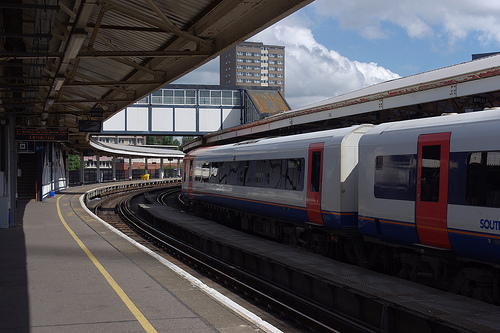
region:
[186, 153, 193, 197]
the door on a passenger train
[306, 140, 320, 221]
the door on a passenger train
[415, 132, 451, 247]
the door on a passenger train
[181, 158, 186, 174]
a window on a passenger train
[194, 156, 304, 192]
windows on a passenger train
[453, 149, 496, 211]
a window on a passenger train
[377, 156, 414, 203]
a window on a passenger train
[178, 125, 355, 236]
a car on a passenger train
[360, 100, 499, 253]
a car on a passenger train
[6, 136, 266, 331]
the loading ramp of a train station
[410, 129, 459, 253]
A red door on a metro train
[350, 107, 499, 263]
A blue, red and gray train car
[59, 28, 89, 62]
A ceiling light fixture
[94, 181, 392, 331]
Solid steel railroad tracks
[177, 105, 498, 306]
Two full train cars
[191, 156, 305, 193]
A set of windows on train car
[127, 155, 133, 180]
A gray support pole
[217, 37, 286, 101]
A tall brown residential building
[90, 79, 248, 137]
A white and gray walkway over the tracks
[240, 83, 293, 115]
A rusted angled roof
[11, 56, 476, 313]
a train in a train station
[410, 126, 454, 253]
door of train is red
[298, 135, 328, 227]
door of train is red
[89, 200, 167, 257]
edge of platform is white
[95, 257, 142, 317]
a white line on the platform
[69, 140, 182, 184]
columns supporting the roof of train station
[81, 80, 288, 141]
a bridge over the railroad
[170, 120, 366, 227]
car of train is white and blue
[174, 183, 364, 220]
side of train has a red stripe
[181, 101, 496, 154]
roof of train is white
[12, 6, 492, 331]
Photo taken during the day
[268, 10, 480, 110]
The sky is clear with clouds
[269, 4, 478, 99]
The clouds are fluffy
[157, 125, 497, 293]
Train on the track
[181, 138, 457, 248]
Red doors on the train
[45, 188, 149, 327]
Yellow lines on the platform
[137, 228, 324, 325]
Train tracks made of metal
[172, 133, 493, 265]
White and blue train with red doors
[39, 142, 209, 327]
Nobody on the platform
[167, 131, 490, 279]
The train is a passenger train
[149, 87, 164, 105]
window is next to window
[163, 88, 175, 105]
window is next to window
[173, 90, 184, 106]
window is next to window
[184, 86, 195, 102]
window is next to window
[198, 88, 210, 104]
window is next to window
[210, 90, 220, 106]
window is next to window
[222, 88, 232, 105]
window is next to window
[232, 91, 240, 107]
window is next to window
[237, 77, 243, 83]
window is next to window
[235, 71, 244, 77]
window is next to window